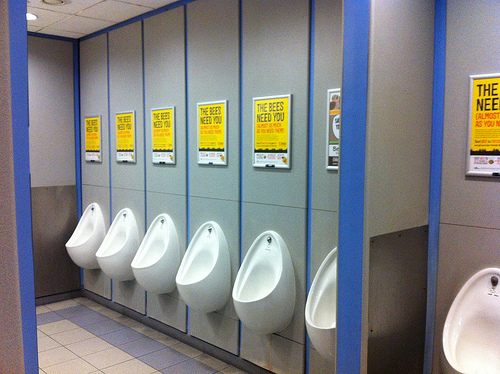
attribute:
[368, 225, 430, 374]
wall — silver, metallic